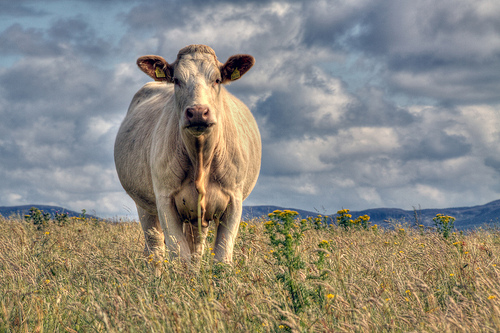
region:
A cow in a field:
[112, 40, 262, 266]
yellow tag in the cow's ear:
[229, 65, 241, 82]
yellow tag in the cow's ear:
[152, 67, 167, 78]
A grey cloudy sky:
[0, 0, 495, 230]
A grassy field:
[0, 205, 496, 325]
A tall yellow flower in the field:
[262, 206, 332, 312]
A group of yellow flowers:
[315, 201, 375, 226]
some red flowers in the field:
[460, 235, 485, 260]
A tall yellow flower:
[430, 206, 450, 236]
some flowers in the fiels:
[20, 207, 81, 289]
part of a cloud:
[408, 108, 428, 129]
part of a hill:
[435, 207, 442, 215]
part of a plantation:
[113, 222, 128, 244]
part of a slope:
[390, 202, 397, 217]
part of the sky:
[80, 126, 97, 141]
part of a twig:
[287, 232, 299, 257]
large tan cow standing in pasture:
[112, 43, 263, 276]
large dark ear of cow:
[136, 54, 173, 84]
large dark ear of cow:
[218, 50, 256, 88]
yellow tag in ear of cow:
[230, 69, 241, 80]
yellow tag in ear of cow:
[152, 66, 166, 81]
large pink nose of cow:
[186, 105, 210, 127]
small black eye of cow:
[213, 78, 220, 86]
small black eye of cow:
[173, 77, 180, 86]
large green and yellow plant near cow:
[259, 206, 317, 317]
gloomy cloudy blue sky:
[0, 0, 499, 220]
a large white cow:
[64, 35, 299, 294]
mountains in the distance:
[2, 177, 491, 247]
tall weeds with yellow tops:
[254, 195, 355, 325]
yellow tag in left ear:
[152, 61, 172, 81]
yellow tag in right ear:
[233, 66, 240, 81]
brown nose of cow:
[181, 100, 221, 142]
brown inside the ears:
[133, 48, 256, 85]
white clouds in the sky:
[8, 5, 499, 189]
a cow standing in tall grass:
[94, 39, 302, 294]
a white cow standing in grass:
[85, 44, 330, 323]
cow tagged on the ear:
[153, 65, 166, 79]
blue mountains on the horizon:
[3, 200, 497, 232]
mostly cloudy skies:
[9, 3, 496, 201]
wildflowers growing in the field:
[263, 208, 328, 313]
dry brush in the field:
[0, 215, 499, 330]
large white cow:
[115, 48, 261, 258]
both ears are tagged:
[138, 53, 251, 85]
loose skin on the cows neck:
[196, 137, 211, 227]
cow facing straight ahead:
[119, 43, 260, 263]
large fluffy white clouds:
[3, 9, 498, 204]